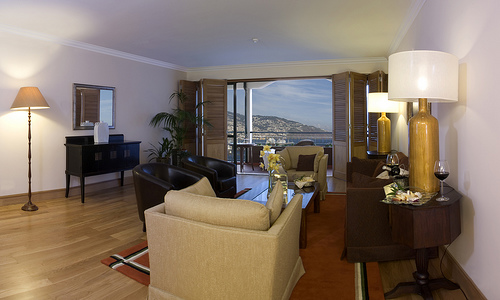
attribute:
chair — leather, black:
[131, 159, 211, 233]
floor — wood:
[2, 174, 462, 299]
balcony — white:
[231, 157, 337, 175]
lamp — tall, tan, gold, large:
[386, 50, 458, 197]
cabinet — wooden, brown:
[64, 131, 142, 202]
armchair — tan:
[141, 176, 307, 300]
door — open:
[226, 81, 237, 166]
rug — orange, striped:
[103, 190, 384, 298]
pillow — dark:
[297, 153, 316, 172]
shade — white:
[388, 49, 457, 104]